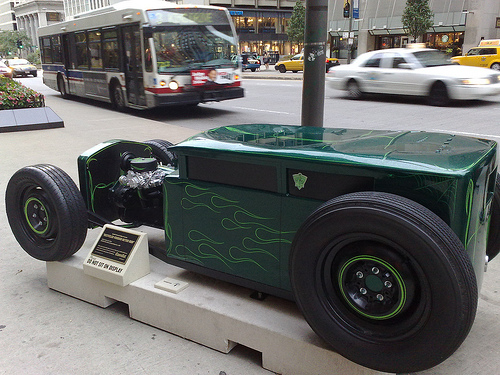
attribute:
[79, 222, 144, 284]
plaque — black, gold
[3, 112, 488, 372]
motorbox — large, green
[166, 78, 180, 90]
light — white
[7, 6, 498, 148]
city street — very busy, filled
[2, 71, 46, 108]
flower beds — raised, ornamental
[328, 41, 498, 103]
taxi cab — white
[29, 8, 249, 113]
bus — moving, large, city transport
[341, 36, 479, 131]
car — white